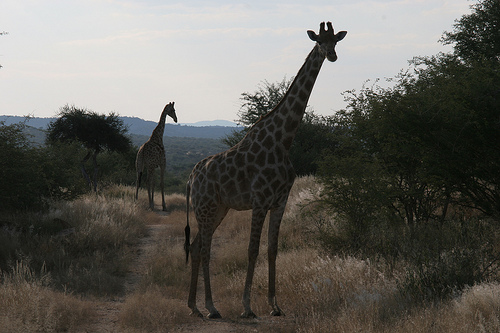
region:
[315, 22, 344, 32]
these are giraffe horns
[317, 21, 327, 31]
this is a horn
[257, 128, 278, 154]
this is a spot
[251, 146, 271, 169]
a brown giraffe spot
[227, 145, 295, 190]
these are the spots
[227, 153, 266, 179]
these are giraffe spots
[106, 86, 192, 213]
this is a giraffe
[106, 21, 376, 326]
these are the giraffes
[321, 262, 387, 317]
this is brown grass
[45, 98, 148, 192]
this is a tree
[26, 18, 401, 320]
Two giraffes standing in a field.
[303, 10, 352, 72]
Head of giraffe in foreground.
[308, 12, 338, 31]
Horns of giraffe in foreground.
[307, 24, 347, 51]
Ears of giraffe in foreground.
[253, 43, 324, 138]
Long neck of giraffe in foreground.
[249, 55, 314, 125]
Mane on neck of giraffe in foreground.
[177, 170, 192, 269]
Tail of giraffe in foreground.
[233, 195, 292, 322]
Front legs of giraffe in foreground.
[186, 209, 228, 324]
Back legs of giraffe in foreground.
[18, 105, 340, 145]
Mountains in the distant.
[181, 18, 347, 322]
a very tall giraffe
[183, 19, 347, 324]
a brown and white giraffe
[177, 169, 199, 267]
a giraffe with a long tail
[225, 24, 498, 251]
an area of green bushes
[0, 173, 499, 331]
a large area of brown grass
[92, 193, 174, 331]
a long dirt trail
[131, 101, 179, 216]
a giraffe looking right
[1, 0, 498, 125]
a clear blue sky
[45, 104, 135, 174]
a wide green tree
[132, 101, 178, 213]
a small brown and white giraffe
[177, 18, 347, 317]
a giraffe in the road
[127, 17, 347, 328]
a couple giraffe in the road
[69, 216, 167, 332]
a grassy dirt road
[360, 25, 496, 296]
leafy green bushes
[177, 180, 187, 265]
the tail of a giraffe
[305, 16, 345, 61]
the head of a giraffe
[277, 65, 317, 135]
the neck of a giraffe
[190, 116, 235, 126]
a mountain in the distance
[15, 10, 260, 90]
a cloudy gray sky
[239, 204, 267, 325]
the front leg of a giraffe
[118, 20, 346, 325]
The giraffes are brown.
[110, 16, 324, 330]
The giraffes are standing.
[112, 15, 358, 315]
The giraffes are spotted.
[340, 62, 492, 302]
The trees are leafy.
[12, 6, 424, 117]
The sky is cloudy.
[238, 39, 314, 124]
The mane is brown.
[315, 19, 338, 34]
The giraffe has two horns.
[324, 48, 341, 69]
His nose is brown.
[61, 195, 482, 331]
The grass is brown.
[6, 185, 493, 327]
The grass is dead.